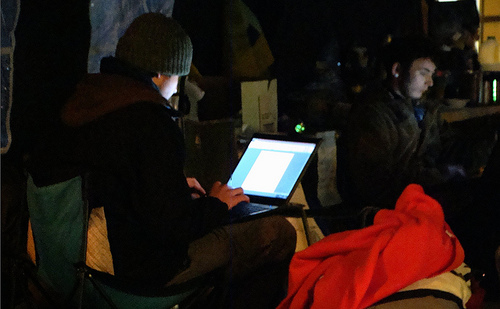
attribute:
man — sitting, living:
[27, 14, 297, 308]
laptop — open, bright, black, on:
[189, 133, 319, 223]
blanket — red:
[271, 184, 467, 308]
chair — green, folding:
[20, 159, 223, 308]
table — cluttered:
[276, 104, 499, 136]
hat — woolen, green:
[113, 12, 192, 75]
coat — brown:
[32, 75, 229, 290]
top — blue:
[486, 35, 495, 41]